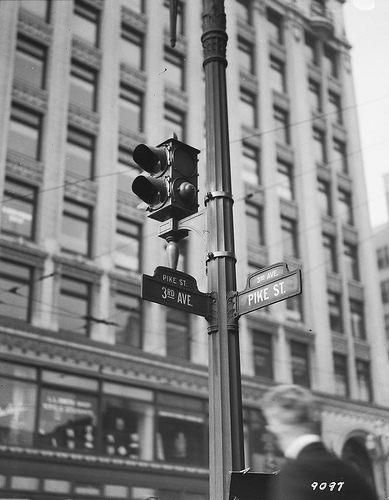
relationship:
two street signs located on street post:
[232, 259, 304, 326] [201, 3, 248, 499]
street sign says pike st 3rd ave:
[139, 265, 208, 319] [160, 271, 193, 309]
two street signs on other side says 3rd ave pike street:
[232, 259, 304, 326] [243, 266, 287, 309]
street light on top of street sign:
[131, 129, 202, 238] [139, 265, 208, 319]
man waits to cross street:
[256, 382, 378, 499] [1, 480, 387, 500]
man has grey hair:
[256, 382, 378, 499] [256, 382, 321, 434]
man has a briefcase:
[256, 382, 378, 499] [228, 469, 280, 499]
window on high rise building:
[267, 9, 285, 48] [1, 2, 388, 496]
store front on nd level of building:
[3, 355, 216, 465] [1, 2, 388, 496]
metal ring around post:
[202, 193, 236, 203] [201, 3, 248, 499]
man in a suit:
[256, 382, 378, 499] [269, 436, 380, 498]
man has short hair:
[256, 382, 378, 499] [256, 382, 321, 434]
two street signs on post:
[136, 259, 304, 323] [201, 3, 248, 499]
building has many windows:
[1, 2, 388, 496] [3, 9, 389, 491]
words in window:
[3, 203, 33, 227] [2, 179, 40, 242]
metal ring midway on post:
[202, 193, 236, 203] [201, 3, 248, 499]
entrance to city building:
[337, 426, 388, 497] [1, 2, 388, 496]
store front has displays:
[3, 355, 216, 465] [3, 382, 190, 459]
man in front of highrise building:
[256, 382, 378, 499] [1, 2, 388, 496]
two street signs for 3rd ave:
[232, 259, 304, 326] [249, 268, 283, 287]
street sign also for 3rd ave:
[139, 265, 208, 319] [160, 287, 194, 309]